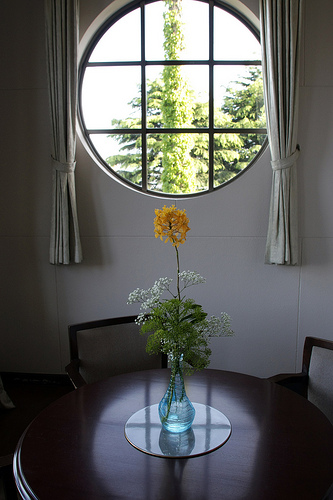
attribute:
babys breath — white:
[179, 268, 206, 288]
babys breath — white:
[197, 312, 235, 338]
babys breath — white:
[125, 277, 173, 323]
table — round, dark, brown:
[12, 368, 330, 499]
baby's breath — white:
[126, 282, 162, 324]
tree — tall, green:
[162, 1, 191, 196]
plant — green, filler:
[144, 305, 204, 356]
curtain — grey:
[253, 1, 303, 266]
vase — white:
[156, 362, 195, 430]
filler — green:
[146, 300, 206, 362]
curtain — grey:
[34, 21, 134, 257]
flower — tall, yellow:
[152, 205, 191, 424]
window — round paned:
[77, 0, 265, 198]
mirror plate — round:
[124, 401, 232, 458]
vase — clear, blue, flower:
[162, 362, 192, 401]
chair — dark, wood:
[58, 313, 180, 386]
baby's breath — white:
[124, 268, 232, 376]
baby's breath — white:
[123, 261, 241, 385]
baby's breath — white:
[135, 293, 162, 313]